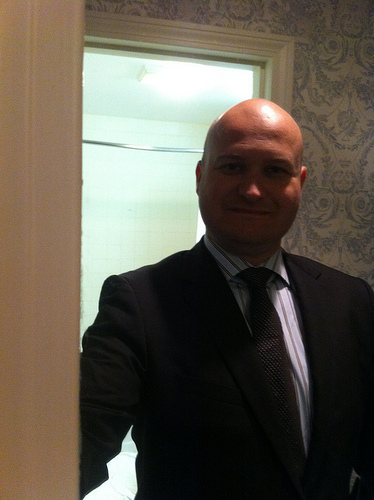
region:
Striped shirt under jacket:
[235, 232, 312, 451]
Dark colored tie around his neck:
[252, 273, 309, 449]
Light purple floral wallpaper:
[291, 21, 372, 252]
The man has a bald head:
[205, 95, 314, 160]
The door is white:
[5, 28, 80, 498]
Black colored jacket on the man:
[139, 351, 271, 491]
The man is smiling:
[206, 192, 293, 220]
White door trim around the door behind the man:
[87, 4, 296, 99]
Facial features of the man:
[193, 95, 305, 242]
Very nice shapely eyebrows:
[210, 143, 307, 174]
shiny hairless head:
[191, 95, 309, 261]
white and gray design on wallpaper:
[83, 2, 373, 273]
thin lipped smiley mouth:
[228, 201, 273, 217]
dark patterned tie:
[237, 262, 306, 460]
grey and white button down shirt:
[201, 238, 321, 464]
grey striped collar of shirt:
[200, 233, 292, 288]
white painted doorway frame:
[1, 1, 82, 497]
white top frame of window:
[85, 9, 296, 62]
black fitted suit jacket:
[80, 246, 372, 496]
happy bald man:
[86, 98, 372, 498]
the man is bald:
[204, 97, 341, 202]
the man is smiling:
[200, 111, 331, 276]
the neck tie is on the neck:
[202, 258, 312, 393]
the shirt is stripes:
[224, 260, 320, 419]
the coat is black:
[113, 277, 216, 450]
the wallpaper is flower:
[319, 48, 359, 199]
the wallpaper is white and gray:
[334, 107, 372, 218]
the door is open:
[12, 65, 75, 447]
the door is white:
[2, 156, 99, 351]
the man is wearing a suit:
[129, 249, 351, 479]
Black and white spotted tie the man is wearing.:
[234, 261, 308, 481]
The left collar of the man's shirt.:
[202, 238, 251, 290]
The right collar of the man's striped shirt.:
[265, 256, 290, 286]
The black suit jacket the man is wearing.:
[79, 248, 371, 498]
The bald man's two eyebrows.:
[213, 142, 295, 173]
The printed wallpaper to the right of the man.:
[286, 41, 372, 262]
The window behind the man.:
[87, 43, 234, 257]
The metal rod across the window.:
[82, 137, 203, 156]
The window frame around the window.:
[84, 10, 297, 97]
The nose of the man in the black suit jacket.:
[240, 177, 273, 205]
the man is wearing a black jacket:
[79, 231, 373, 496]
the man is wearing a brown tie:
[231, 263, 309, 492]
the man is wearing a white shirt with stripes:
[201, 226, 313, 470]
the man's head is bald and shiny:
[196, 92, 328, 153]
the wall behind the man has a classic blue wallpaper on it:
[86, 0, 372, 290]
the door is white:
[0, 1, 86, 497]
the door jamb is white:
[80, 8, 293, 359]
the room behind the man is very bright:
[80, 48, 254, 498]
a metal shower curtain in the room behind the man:
[82, 137, 210, 155]